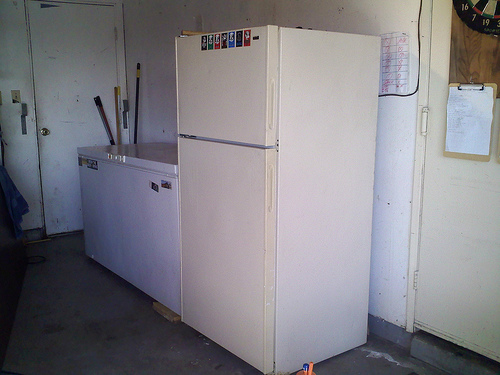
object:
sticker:
[241, 27, 253, 47]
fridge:
[171, 22, 386, 374]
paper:
[376, 31, 409, 97]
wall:
[122, 0, 421, 352]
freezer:
[75, 140, 183, 318]